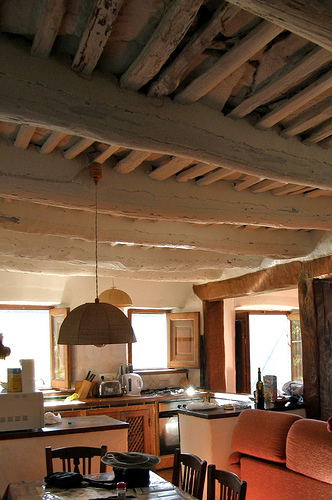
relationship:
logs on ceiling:
[2, 3, 330, 244] [0, 0, 330, 221]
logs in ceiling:
[2, 3, 330, 244] [0, 0, 330, 221]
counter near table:
[183, 399, 231, 424] [67, 462, 170, 500]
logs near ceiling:
[2, 3, 330, 244] [0, 0, 330, 221]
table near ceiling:
[67, 462, 170, 500] [0, 0, 330, 221]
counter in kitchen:
[183, 399, 231, 424] [8, 307, 294, 423]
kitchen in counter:
[8, 307, 294, 423] [183, 399, 231, 424]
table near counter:
[67, 462, 170, 500] [183, 399, 231, 424]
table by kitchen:
[67, 462, 170, 500] [8, 307, 294, 423]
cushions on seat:
[227, 403, 330, 489] [224, 453, 328, 498]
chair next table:
[201, 461, 249, 499] [1, 466, 196, 499]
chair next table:
[168, 443, 209, 495] [1, 466, 196, 499]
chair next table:
[41, 440, 108, 478] [1, 466, 196, 499]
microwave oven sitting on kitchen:
[0, 385, 50, 438] [8, 307, 294, 423]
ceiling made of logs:
[0, 0, 330, 221] [2, 3, 330, 244]